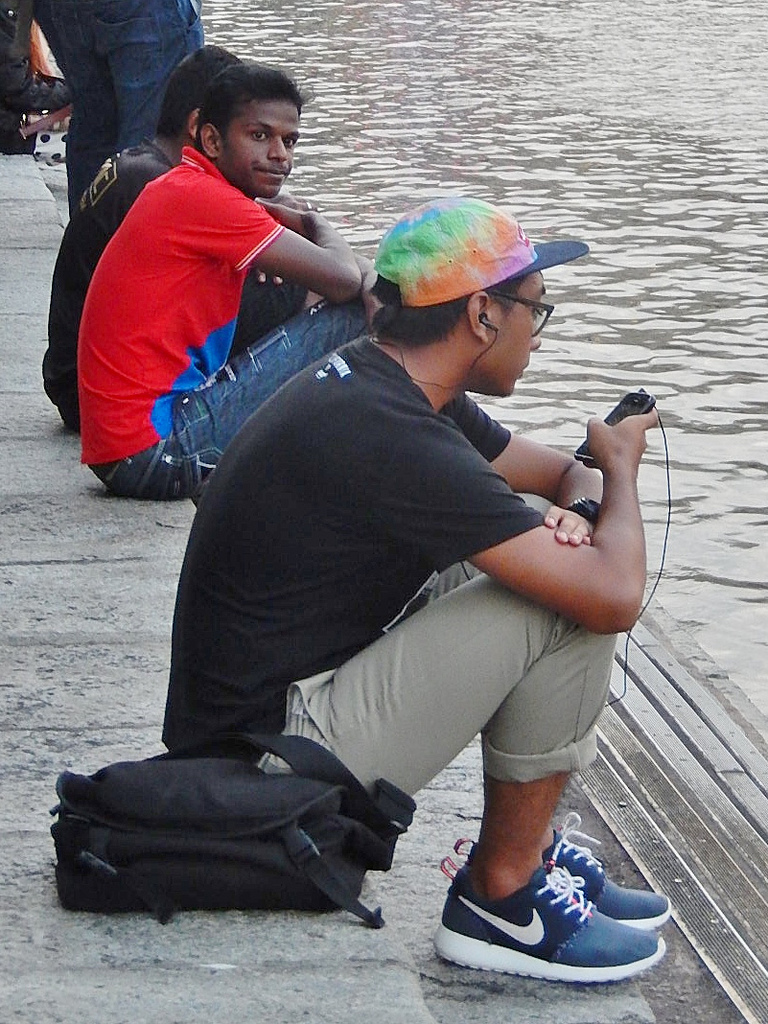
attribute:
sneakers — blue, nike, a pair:
[433, 826, 684, 981]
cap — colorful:
[374, 192, 589, 308]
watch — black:
[564, 494, 611, 522]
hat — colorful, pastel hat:
[377, 191, 592, 309]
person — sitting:
[160, 193, 675, 986]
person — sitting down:
[78, 61, 383, 496]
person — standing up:
[41, 41, 243, 431]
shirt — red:
[72, 163, 321, 482]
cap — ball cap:
[353, 164, 600, 362]